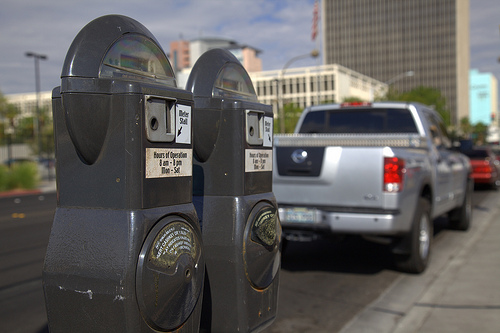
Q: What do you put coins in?
A: Meter.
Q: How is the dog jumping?
A: No dog.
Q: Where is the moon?
A: No moon.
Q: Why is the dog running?
A: No dog.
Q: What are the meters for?
A: Pay to park.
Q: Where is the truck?
A: In the street.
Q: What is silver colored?
A: The truck.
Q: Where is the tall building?
A: Straight away distance.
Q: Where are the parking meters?
A: On the sidewalk.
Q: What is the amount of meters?
A: Two.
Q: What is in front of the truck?
A: The car.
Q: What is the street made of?
A: Tar.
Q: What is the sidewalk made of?
A: Cement.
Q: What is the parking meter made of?
A: Metal.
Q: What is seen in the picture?
A: Two parking meters by the city street.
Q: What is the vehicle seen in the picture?
A: A silver pick up truck.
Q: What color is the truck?
A: Silver.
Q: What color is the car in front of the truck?
A: Red.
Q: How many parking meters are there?
A: Two.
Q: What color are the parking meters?
A: Gray.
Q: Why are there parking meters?
A: To regulate parking times.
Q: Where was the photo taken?
A: On the street.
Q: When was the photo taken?
A: Daytime.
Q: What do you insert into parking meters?
A: Coins.